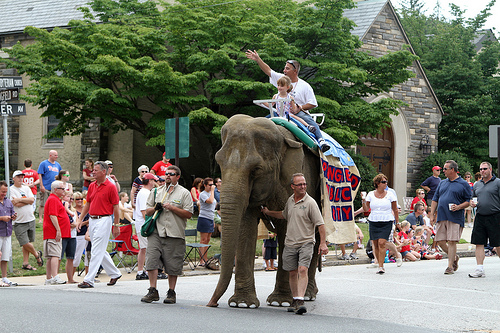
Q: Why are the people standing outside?
A: They are watching the parade.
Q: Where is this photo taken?
A: Outside at a parade.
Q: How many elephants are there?
A: One.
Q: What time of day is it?
A: Daytime.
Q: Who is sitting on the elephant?
A: A man and woman.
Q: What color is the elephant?
A: Gray.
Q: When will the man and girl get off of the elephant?
A: After the parade has ended.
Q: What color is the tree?
A: Green.